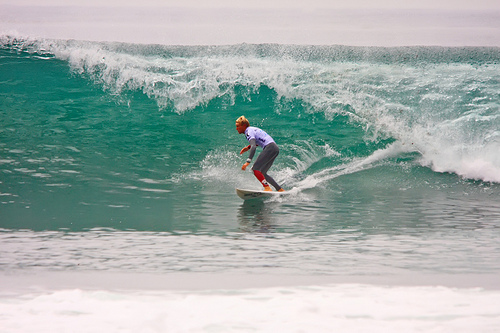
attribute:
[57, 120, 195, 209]
water — green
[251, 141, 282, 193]
pants — grey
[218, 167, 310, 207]
surf board. — white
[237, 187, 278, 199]
board — long, white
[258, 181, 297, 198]
feet — bare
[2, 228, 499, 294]
bubbles — calm 